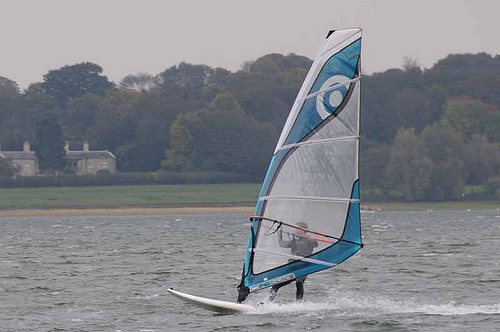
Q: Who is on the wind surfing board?
A: A man.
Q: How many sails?
A: One.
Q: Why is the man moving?
A: The wind.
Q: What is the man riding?
A: A windsurfing board.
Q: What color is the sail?
A: White and blue.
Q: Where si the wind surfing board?
A: In the water.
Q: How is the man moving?
A: The wind.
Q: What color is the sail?
A: Blue and white.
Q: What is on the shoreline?
A: Trees.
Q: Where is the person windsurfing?
A: Lake.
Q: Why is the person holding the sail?
A: Pleasure.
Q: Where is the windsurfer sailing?
A: River.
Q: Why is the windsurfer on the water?
A: Pleasure.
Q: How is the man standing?
A: On both feet.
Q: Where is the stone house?
A: Shoreline.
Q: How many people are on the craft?
A: One.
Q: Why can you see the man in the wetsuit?
A: Because the sail is clear.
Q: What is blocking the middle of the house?
A: A tree.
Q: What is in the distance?
A: Trees.